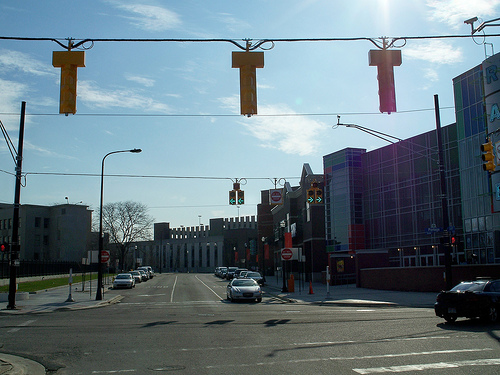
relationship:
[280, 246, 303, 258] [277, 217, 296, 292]
sign on pole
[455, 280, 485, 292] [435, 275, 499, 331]
windshield of car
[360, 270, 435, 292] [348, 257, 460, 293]
red paint on wall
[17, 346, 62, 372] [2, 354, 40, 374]
cracks in sidewalk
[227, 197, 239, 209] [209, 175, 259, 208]
arrow on traffic light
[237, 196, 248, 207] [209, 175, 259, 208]
arrow on traffic light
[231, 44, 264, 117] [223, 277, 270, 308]
street light on car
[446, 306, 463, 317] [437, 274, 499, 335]
license plate on back of a car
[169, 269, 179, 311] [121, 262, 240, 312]
lines on road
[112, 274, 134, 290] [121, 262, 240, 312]
car on road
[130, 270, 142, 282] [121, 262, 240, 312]
car on road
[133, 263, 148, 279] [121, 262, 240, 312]
car on road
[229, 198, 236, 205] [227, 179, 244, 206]
arrow on street light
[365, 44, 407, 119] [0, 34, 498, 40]
street light on line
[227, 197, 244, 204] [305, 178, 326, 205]
signal on traffic signal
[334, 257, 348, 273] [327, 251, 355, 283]
symbol on wall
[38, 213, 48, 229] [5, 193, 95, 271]
window on building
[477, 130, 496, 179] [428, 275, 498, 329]
light on car